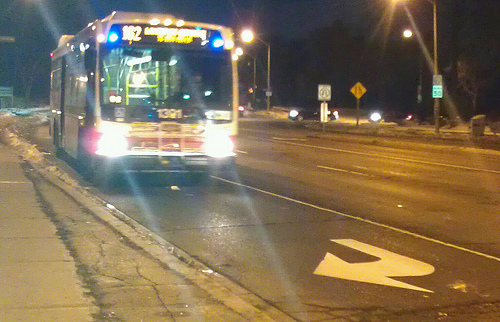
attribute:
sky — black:
[86, 1, 386, 38]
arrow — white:
[312, 235, 436, 296]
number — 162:
[122, 25, 144, 42]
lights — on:
[96, 128, 234, 161]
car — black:
[287, 105, 340, 124]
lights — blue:
[108, 32, 225, 50]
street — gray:
[33, 122, 499, 321]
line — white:
[209, 174, 498, 263]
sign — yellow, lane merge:
[349, 81, 368, 100]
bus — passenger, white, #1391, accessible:
[47, 8, 241, 183]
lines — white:
[210, 134, 499, 266]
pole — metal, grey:
[256, 36, 275, 112]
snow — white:
[0, 105, 80, 186]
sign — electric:
[122, 25, 208, 45]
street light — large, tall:
[239, 28, 272, 112]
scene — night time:
[0, 0, 499, 321]